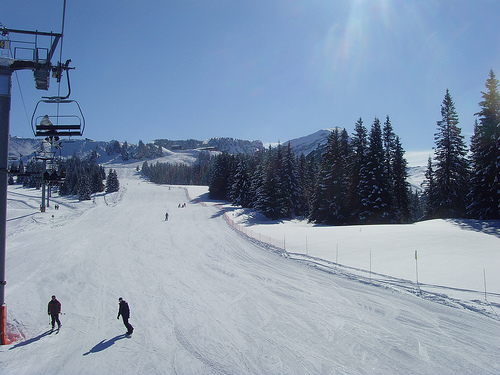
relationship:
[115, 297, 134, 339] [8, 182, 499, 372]
person on snow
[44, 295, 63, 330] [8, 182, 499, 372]
people on snow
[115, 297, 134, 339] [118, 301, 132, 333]
person wearing clothing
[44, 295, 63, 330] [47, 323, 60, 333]
people on skis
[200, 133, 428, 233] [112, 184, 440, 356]
trees lining slope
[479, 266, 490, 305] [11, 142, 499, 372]
pole on edge of course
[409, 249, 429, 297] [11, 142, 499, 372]
pole on edge of course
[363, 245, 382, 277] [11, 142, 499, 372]
pole on edge of course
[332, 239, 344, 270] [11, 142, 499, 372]
pole on edge of course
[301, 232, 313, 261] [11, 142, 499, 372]
pole on edge of course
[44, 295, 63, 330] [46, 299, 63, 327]
people wearing clothes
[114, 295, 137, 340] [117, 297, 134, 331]
person wearing clothes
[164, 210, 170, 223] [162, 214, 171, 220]
person wearing clothes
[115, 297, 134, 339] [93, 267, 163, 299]
person skiing snow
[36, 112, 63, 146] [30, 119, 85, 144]
person sitting on ski lift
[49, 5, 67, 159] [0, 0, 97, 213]
cable holding ski lift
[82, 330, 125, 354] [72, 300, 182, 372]
shadow of snowboarder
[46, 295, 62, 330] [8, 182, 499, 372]
people skiing on snow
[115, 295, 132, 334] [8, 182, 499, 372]
people skiing on snow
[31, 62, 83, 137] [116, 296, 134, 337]
ski lift above people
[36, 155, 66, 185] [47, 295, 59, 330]
ski lift above people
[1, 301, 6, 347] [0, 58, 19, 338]
base of beam